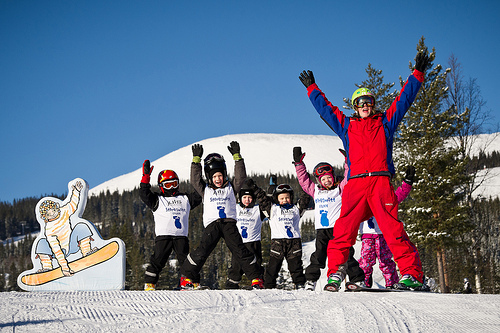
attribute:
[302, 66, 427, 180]
jacket — red, blue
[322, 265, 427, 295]
boots — green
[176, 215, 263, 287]
pants — child's, snow pants, black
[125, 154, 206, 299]
child — small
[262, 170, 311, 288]
child — small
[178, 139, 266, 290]
child — small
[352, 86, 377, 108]
helmet — yellow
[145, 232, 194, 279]
pants — snow pants, black, child's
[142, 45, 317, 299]
children shirts — white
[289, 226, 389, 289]
childs pants — snow pants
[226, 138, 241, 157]
glove — black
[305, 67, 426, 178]
coat — red, blue, winter 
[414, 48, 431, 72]
hands — up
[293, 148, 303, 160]
hands — up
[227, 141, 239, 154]
hands — up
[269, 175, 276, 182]
hands — up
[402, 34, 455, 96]
gloves — black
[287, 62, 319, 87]
gloves — black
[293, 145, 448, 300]
pants — pink, snow pants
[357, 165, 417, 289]
child — small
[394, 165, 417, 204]
arm — up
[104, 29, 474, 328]
snowboarders — children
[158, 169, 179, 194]
helmet — skiier's, red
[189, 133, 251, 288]
child — small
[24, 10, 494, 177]
sky — neat, Blue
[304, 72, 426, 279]
skisuit — pink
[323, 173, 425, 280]
pants — red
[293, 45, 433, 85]
gloves — black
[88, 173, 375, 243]
participation vest — white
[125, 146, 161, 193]
glove — red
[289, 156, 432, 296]
pants — red, snow pants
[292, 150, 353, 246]
coat — pink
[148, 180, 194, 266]
child — small